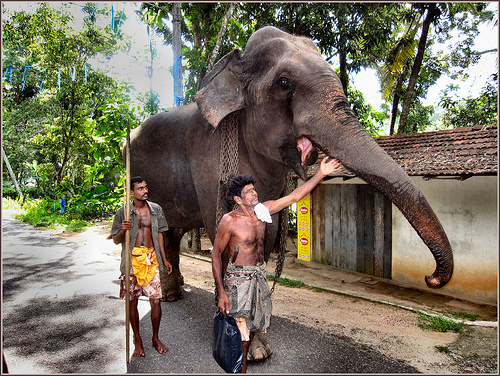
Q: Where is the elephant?
A: On the road.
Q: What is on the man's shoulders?
A: Towel.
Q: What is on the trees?
A: Leaves.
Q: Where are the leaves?
A: On the trees.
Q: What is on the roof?
A: Shingles.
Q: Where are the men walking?
A: Road.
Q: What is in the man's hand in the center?
A: Black bag.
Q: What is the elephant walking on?
A: Paved road.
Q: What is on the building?
A: Shingled roof.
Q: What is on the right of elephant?
A: Building.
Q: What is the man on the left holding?
A: Long pole.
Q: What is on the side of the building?
A: Boards.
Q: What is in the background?
A: Trees.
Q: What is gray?
A: Elephant.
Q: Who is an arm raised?
A: Man in front.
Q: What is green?
A: Trees.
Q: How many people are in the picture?
A: Two.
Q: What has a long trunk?
A: The elephant.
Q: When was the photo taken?
A: During the day.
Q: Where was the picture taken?
A: At a wildlife preserve.